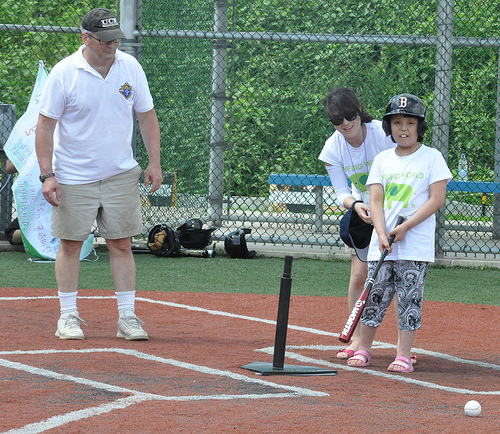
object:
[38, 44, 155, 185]
shirt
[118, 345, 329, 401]
line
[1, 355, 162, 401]
line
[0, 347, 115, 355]
line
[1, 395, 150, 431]
line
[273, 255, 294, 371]
pole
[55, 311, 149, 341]
shoes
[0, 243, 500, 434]
field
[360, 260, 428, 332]
black pants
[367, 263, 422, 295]
white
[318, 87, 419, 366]
girl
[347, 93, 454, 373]
girl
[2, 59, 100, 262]
bags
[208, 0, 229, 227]
pole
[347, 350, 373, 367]
pink shoe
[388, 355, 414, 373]
pink shoe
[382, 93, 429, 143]
helmet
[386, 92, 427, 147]
head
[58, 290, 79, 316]
man socks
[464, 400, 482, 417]
ball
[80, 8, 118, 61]
head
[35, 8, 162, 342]
man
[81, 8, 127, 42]
cap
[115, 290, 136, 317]
sock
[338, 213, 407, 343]
bat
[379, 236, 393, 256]
hand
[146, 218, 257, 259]
bags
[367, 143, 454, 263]
shirt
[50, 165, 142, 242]
shorts